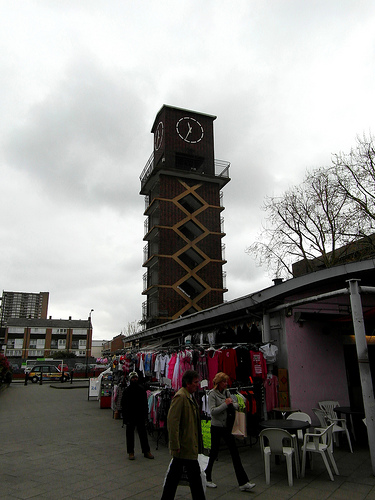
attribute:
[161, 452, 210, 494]
shopping bag — white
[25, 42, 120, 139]
cars — ominous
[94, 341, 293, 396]
rack — long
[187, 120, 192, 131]
hour hand — white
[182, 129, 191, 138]
minute hand — white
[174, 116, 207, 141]
clock — round, white 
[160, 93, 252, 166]
tower — large, dark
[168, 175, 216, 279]
pattern — diamond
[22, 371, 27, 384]
post — black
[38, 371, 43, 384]
post — black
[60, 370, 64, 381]
post — black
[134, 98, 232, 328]
tower — brown 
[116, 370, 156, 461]
man — watching, alone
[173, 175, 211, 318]
design — light brown , diamond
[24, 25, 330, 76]
sky — cloudy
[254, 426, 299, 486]
chair — plastic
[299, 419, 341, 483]
chair — plastic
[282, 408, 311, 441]
chair — plastic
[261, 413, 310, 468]
table — small, round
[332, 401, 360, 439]
table — small, round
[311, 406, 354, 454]
chair — plastic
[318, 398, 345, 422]
chair — plastic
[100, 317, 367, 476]
shopping area — large, outdoor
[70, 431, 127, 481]
tiles — square